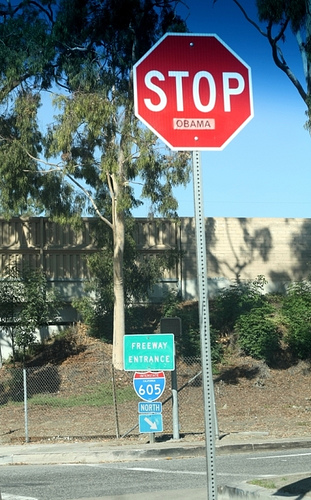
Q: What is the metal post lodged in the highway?
A: A stop sign.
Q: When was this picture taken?
A: During the daylight.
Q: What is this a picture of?
A: Highway signs.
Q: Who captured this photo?
A: A photographer.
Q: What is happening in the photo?
A: A traffic sign is directing motorists to freeway entrance.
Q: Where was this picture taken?
A: At an intersection.